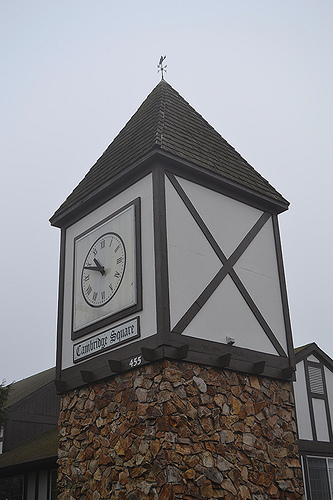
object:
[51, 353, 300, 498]
wall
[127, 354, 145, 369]
455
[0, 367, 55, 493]
building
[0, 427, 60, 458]
roof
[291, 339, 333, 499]
building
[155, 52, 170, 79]
weather vein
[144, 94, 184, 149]
shingles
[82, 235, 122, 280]
22:49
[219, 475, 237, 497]
stone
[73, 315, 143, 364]
sign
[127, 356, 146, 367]
number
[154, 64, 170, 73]
arrows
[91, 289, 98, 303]
roman numerals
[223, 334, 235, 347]
light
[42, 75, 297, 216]
roof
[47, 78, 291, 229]
roof top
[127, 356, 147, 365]
number 455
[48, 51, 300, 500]
building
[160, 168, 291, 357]
x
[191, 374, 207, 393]
rock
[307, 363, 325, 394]
air vent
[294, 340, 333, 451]
attic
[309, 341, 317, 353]
peak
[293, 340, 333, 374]
roof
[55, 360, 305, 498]
base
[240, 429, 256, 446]
rock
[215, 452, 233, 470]
rock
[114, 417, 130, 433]
rock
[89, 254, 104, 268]
hand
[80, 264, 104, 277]
hand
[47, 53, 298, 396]
clock tower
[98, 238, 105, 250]
roman numeral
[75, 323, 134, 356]
cambridge square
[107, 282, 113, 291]
roman numeral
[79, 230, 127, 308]
clock face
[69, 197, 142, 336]
clock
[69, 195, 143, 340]
square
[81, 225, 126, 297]
10:49